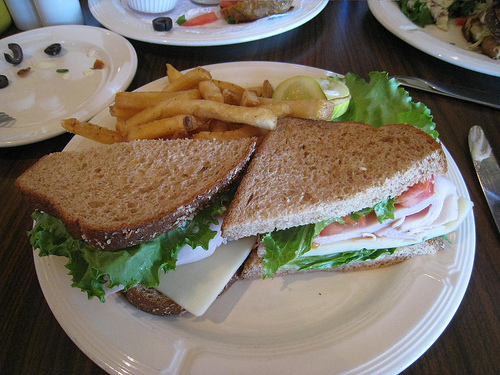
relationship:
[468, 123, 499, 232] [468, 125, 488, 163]
knife has butter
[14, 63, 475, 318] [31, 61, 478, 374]
food on plate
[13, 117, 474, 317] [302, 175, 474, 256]
sandwich has meat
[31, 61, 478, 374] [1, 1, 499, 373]
plate on top of table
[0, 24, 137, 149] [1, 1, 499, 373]
plate on top of table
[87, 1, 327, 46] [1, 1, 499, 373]
plate on top of table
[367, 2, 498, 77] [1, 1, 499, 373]
plate on top of table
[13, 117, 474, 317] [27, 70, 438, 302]
sandwich with lettuce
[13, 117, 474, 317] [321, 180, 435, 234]
sandwich with tomato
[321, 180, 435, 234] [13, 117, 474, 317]
tomato on sandwich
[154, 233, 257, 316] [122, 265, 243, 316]
cheese on bread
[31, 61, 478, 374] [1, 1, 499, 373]
plate on table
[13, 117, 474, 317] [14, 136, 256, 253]
sandwich on bread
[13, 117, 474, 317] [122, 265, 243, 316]
sandwich on bread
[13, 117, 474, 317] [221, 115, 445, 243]
sandwich on bread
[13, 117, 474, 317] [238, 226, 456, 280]
sandwich on bread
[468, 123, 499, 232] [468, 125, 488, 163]
knife with butter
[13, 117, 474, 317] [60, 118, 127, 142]
sandwich and french fry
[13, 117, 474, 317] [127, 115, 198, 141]
sandwich and french fry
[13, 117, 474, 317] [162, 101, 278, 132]
sandwich and french fry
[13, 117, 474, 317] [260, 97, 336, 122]
sandwich and french fry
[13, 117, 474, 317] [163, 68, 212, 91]
sandwich and french fry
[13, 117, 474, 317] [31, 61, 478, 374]
sandwich on plate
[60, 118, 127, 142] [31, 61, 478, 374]
french fry on plate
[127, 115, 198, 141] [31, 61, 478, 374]
french fry on plate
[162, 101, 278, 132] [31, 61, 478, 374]
french fry on plate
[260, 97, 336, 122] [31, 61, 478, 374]
french fry on plate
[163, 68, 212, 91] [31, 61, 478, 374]
french fry on plate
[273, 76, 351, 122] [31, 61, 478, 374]
pickle on plate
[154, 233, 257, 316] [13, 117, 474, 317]
cheese on sandwich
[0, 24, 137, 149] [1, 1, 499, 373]
plate on table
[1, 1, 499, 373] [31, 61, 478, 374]
table with plate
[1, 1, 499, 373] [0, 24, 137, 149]
table with plate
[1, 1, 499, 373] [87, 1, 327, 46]
table with plate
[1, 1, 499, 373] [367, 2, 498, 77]
table with plate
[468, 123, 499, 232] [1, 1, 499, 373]
knife on table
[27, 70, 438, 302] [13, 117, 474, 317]
lettuce on sandwich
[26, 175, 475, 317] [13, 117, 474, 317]
inside of sandwich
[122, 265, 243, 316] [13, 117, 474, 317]
bread of sandwich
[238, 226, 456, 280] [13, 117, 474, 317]
bread of sandwich